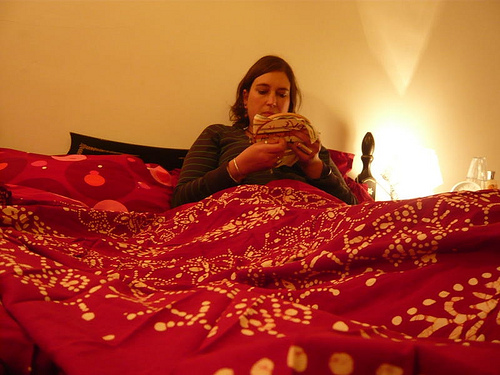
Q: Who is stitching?
A: The woman in bed.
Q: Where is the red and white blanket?
A: On the woman.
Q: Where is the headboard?
A: Behind the woman.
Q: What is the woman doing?
A: Stitching.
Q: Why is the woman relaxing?
A: Stitching in bed.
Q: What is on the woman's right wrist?
A: Bracelet.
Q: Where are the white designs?
A: Blanket.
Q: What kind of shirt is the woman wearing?
A: A striped long sleeved shirt.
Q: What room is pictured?
A: A bedroom.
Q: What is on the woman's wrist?
A: A silver bracelet.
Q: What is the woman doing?
A: Sewing.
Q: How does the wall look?
A: Yellow.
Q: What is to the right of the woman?
A: A bright light.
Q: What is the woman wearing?
A: Several rings.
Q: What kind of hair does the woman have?
A: Brown hair.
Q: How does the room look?
A: Dim.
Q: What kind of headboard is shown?
A: A wooden headboard.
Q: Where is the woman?
A: In bed.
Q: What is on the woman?
A: A blanket.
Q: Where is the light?
A: In the corner.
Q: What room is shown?
A: Bedroom.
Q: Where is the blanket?
A: On the bed.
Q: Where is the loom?
A: In the woman's hands.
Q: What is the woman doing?
A: Cross stitch.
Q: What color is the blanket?
A: Red.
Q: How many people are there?
A: One.